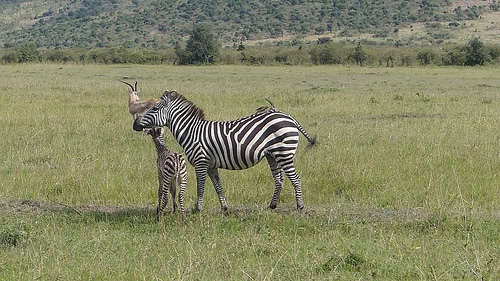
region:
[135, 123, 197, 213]
Baby zebra next to it's mother.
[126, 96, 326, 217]
Adult zebra over the baby.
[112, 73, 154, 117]
Antelope in the background.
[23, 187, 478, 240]
Dry patch of grass.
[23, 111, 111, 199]
The grass is green.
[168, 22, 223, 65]
Tree in the background.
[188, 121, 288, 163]
The zebra is black and white.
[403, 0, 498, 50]
Dry grass in the background.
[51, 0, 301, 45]
Large amount of trees in the background.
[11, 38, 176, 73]
Bushes around the tree.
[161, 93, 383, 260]
the zebra has stripes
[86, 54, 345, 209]
the zebra has stripes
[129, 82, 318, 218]
The full grown zebra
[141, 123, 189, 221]
The baby zebra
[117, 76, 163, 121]
The gazelle behind the zebras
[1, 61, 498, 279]
The grass field the zebras are on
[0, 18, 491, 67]
The trees at the edge of the field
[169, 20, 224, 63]
The tallest tree at the edge of the field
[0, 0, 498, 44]
The hill in the background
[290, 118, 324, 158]
The tail of the adult zebra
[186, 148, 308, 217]
The legs of the adult zebra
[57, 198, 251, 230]
The shadows of the zebras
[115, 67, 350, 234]
Two zebras are together.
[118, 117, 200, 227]
The zebra is a baby.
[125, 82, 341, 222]
The zebra is the mother.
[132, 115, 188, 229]
The baby smells his mother.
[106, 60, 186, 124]
An antelope is behind the zebras.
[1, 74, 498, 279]
The elephants stand in grass.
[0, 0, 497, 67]
A hill is in the background.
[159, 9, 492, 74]
Trees are in the background.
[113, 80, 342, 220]
The zebra faces the left.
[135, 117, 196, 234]
The baby zebra faces away from the camera.